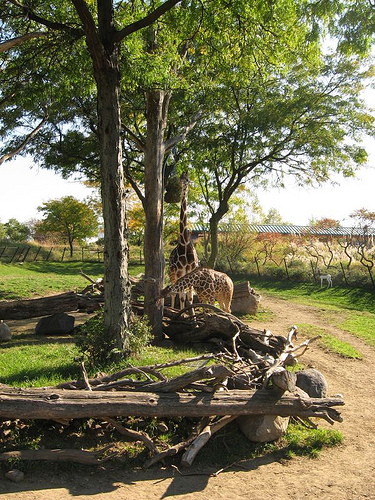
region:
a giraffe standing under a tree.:
[152, 139, 247, 331]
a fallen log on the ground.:
[0, 378, 350, 428]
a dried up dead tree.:
[149, 288, 325, 492]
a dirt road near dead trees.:
[0, 292, 373, 496]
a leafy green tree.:
[0, 0, 326, 368]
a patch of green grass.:
[249, 270, 373, 358]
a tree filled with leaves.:
[28, 188, 107, 260]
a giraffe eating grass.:
[148, 251, 249, 312]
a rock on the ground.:
[287, 365, 332, 396]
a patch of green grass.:
[278, 418, 353, 460]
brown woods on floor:
[73, 345, 313, 480]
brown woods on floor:
[88, 222, 280, 436]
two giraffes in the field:
[170, 162, 250, 317]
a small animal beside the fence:
[304, 267, 344, 294]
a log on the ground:
[26, 377, 324, 449]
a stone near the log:
[293, 369, 333, 397]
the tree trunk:
[87, 26, 143, 337]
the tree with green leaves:
[18, 7, 358, 177]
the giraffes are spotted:
[165, 159, 243, 317]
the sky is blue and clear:
[4, 167, 28, 195]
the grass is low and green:
[15, 360, 60, 379]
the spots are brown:
[175, 235, 206, 280]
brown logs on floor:
[80, 358, 310, 442]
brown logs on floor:
[133, 367, 308, 487]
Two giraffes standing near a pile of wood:
[161, 166, 242, 332]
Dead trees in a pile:
[1, 350, 341, 473]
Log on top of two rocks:
[0, 290, 80, 342]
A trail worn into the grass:
[265, 294, 373, 405]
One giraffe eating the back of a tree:
[139, 257, 241, 319]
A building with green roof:
[181, 212, 366, 241]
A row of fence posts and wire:
[0, 240, 93, 266]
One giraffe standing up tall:
[152, 167, 222, 318]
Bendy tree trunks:
[282, 208, 374, 271]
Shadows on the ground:
[1, 440, 327, 496]